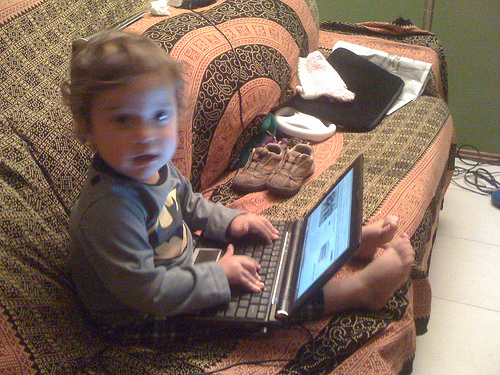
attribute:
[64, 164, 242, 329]
shirt — gray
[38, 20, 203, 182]
hair — blonde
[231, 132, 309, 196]
shoes — pair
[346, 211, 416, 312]
feet — bare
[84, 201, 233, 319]
shirt — long 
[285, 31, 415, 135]
pillow — black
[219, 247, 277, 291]
keys — grey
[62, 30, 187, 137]
hair — brown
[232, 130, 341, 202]
shoes — kids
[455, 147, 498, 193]
cords — black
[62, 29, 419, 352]
child — tiny, pro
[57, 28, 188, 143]
hair — brown 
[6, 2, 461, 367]
couch — brown, pink, many colors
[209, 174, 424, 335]
laptop — on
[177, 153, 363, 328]
laptop — black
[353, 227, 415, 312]
feet — bare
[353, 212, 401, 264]
feet — bare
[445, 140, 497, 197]
power cord — black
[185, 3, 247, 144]
power cord — black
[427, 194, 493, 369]
floor — white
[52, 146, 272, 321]
shirt — gray, yellow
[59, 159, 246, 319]
shirt — gray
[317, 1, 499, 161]
wall — green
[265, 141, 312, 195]
shoe — brown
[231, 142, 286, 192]
shoe — brown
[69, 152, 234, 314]
shirt — long , gray 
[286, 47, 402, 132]
cover — black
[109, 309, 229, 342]
pants — plaid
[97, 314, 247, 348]
pants — plaid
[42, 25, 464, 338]
child — little, blurry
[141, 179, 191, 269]
symbol — Batman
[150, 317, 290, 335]
lap — kid's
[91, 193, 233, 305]
shirt — long sleeved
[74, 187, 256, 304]
shirt — long sleeved, gray